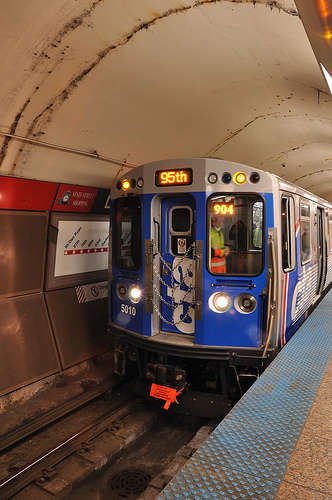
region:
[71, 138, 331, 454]
Underground subway train on tracks.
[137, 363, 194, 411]
Red sign provides danger information.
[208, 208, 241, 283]
Train worker orange green safety clothing.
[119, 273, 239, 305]
Two bright lights shine.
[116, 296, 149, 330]
Number 5010 bottom left corner.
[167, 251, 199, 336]
Train line cta white letters.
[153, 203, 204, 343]
Metal hanging chains prevent entry.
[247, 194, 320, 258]
Passengers seen through windows.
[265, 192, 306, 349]
Train colors red, white and blue.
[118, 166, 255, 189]
Number 95th bordered yellow light.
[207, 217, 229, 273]
a working on train in orange and yellow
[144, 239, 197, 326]
several links of chain in front of train door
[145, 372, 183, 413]
bright orange sign on bottom of train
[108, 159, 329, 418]
a blue and silver train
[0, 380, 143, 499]
a set of train tracks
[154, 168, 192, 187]
a led display on top of train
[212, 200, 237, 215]
a train number indicator display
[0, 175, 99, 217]
a red sign on a subway wall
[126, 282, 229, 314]
a set of headlights on a train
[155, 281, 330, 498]
a blue bump steel grate on edge of train track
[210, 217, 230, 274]
A person standing inside the train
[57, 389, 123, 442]
A railway track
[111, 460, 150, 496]
A metallic lid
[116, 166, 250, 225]
Rear lights of a train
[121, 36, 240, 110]
A roof in the photo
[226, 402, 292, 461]
A floor with tiles next to the rail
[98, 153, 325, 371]
A train in the photo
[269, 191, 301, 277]
A train window.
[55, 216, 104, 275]
Posters on the wall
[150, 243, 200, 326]
Chains on the train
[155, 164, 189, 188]
95th orange yellow light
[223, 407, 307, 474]
blue painted stripe circles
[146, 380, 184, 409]
orange sign with black letters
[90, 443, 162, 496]
sewer opening on bottom of train track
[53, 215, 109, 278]
train station label stops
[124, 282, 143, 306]
bright white train light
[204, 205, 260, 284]
man inside the window of a train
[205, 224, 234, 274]
neon yellow and orange vest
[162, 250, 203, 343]
white CTA letters on a train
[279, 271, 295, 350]
white and red stripes on a train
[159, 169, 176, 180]
The number 95 on the train's marquee display.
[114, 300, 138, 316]
The number 510 on the front of the train.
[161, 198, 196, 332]
The door on the front of the train.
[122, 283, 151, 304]
The left headlight of the train.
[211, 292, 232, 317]
The right headlight of the train.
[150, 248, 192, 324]
The linked chain in front of the train door.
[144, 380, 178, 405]
The red tag on the front of the train.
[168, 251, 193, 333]
The letters CTA on the train's door.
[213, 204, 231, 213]
The number 904 on the illuminated sign.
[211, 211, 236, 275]
The person standing inside of the train in a green vest.